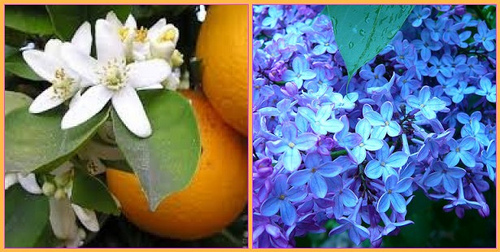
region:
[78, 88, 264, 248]
orange is round and orange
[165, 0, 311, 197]
orange is round and orange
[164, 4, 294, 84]
orange is round and orange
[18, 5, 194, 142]
White flowers over oranges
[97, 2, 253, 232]
Two oranges under white flowers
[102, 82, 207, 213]
Green leave under white flower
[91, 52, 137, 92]
Center of flower is yellow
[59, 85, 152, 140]
Petals of flower is white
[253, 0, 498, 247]
Flowers are purple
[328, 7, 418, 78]
Green leave over purple flowers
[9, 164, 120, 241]
White flower next to oranges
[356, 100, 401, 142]
Small purple flower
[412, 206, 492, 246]
Green leaves below purple flowers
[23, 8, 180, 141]
the white flowers next to the oranges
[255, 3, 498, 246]
many light blue flowers next to a green leaf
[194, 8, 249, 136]
an orange next to the flowers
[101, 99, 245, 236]
another orange behind some green leaves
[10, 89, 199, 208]
a few green leaves by the flowers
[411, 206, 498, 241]
a dark spot under the blue flowers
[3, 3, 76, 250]
more green leaves in the side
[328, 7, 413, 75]
a green leaf above the flowers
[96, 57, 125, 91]
the center of the white flower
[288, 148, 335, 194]
a little blue flower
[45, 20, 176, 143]
white flower next to the orange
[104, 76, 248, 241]
orange next to the white flower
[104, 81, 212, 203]
the leaf is touching the flower and the orange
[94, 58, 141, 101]
middle section of the flower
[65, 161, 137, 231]
green leaf is folded toward the orange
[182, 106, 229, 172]
small specs on the orange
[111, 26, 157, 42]
yellow parts of the white flower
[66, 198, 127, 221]
brown parts of the leaf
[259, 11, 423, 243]
many blueish purple fllowers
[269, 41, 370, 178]
the flowers are small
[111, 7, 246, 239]
two oranges next to each other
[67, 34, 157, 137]
flowers with white pedals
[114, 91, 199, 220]
green leaf attached to flower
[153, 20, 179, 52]
yellow nectar in white flower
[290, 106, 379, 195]
small flowers with 4 pedals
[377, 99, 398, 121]
pedal on blue flowers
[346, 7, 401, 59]
leaf with water drops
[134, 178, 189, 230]
pointed tip of leaf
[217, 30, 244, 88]
dimpled skin of orange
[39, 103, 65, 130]
shadow of flower pedal